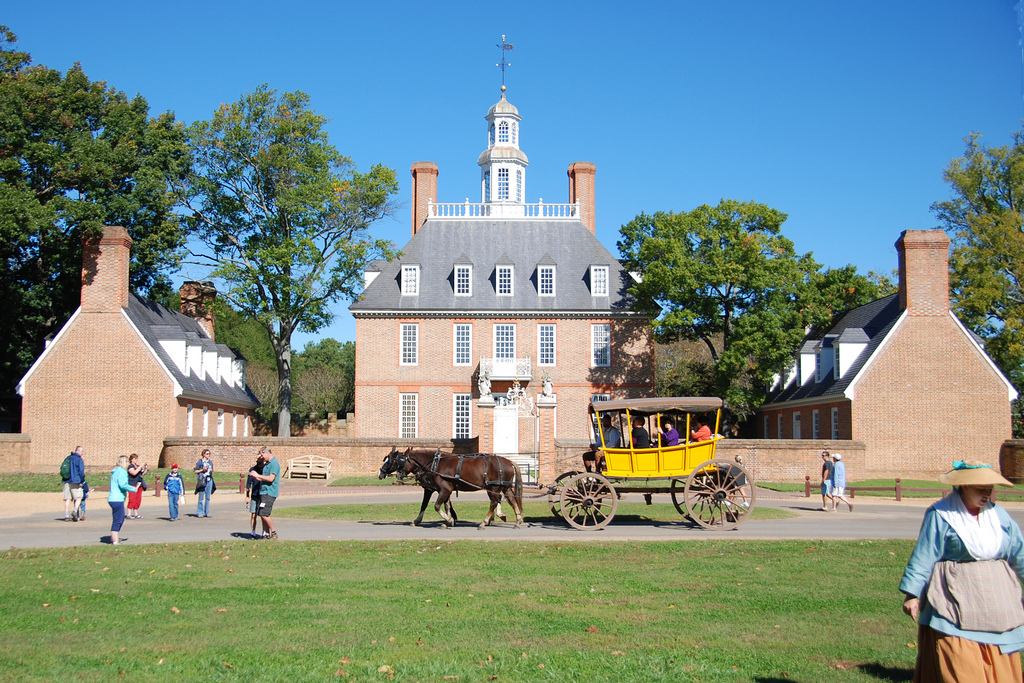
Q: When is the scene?
A: Daytime.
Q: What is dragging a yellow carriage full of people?
A: Two horse.